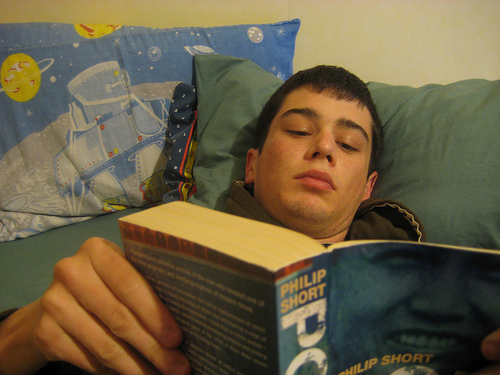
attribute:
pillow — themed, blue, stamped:
[1, 22, 295, 243]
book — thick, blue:
[120, 200, 500, 375]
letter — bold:
[283, 299, 328, 350]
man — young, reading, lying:
[244, 61, 383, 242]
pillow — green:
[367, 81, 500, 249]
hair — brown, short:
[256, 67, 380, 175]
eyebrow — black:
[282, 105, 319, 117]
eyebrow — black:
[336, 118, 371, 142]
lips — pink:
[295, 169, 339, 193]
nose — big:
[306, 129, 338, 166]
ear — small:
[244, 147, 258, 185]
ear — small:
[364, 172, 378, 205]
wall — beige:
[292, 1, 500, 88]